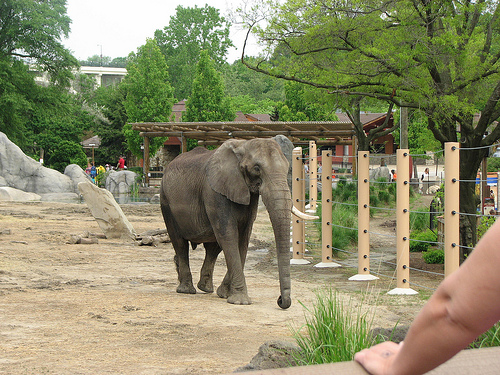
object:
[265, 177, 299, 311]
trunk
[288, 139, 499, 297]
fencing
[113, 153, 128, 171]
people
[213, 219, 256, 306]
legs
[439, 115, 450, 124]
leaves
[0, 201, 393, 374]
floor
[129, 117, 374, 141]
roof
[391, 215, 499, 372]
arm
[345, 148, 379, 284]
post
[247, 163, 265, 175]
eye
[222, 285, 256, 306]
foot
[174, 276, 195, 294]
foot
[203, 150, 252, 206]
ear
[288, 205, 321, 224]
tusk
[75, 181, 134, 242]
rock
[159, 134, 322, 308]
elephant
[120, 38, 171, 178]
pine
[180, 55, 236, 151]
pine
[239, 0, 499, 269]
tree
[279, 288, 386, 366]
grass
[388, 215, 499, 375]
person's arm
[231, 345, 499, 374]
fence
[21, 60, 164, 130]
building